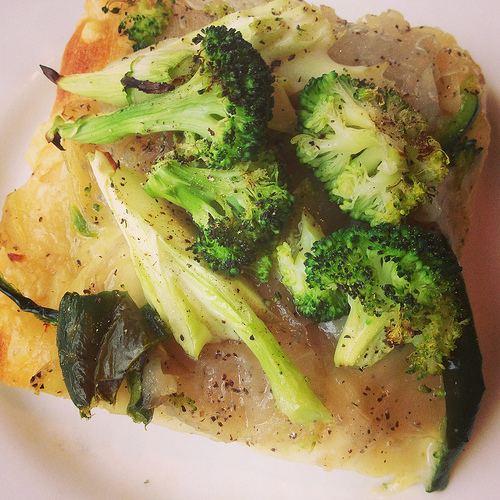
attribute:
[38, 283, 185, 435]
vegetable — cooked, green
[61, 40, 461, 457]
vegetables — pile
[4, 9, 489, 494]
plate — white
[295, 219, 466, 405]
broccolo — green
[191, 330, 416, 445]
meat — pink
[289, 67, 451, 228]
broccoli — toasted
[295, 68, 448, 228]
broccoli floret — browned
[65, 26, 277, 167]
broccoli spear — green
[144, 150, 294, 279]
broccoli spear — green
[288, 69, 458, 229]
broccoli spear — green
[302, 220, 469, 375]
broccoli spear — green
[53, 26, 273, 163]
vegetable — green leaf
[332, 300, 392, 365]
broccoli stalk — light green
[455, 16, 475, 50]
background — white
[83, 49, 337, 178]
floret — green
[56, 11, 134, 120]
bread — toasted